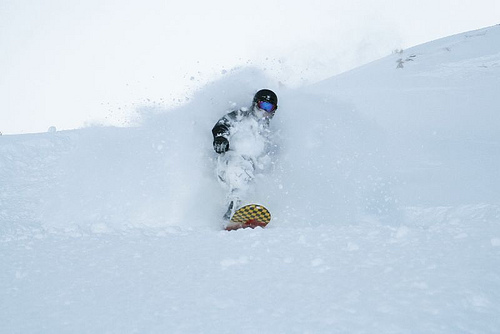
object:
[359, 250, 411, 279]
snow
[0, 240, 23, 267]
snow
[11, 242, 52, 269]
snow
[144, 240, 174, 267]
snow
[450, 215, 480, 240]
snow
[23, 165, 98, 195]
snow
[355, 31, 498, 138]
mountain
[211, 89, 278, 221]
man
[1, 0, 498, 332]
hill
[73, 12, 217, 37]
cloudy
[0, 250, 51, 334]
snow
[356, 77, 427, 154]
snow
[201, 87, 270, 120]
snow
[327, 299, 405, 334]
snow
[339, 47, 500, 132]
white snow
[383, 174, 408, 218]
ground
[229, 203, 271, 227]
board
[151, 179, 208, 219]
snow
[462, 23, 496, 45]
snow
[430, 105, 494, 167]
snow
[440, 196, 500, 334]
slope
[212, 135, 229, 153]
gloves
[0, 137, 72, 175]
snow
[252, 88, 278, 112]
helmet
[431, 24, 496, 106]
ground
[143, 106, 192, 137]
snow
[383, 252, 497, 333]
snow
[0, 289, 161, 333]
ground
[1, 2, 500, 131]
sky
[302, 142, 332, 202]
snow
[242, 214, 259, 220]
checkered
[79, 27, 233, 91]
clouds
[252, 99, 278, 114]
goggles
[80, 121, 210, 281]
hillside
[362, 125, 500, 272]
hillside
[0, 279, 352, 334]
slope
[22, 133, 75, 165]
snow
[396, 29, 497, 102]
slopes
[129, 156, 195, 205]
snow